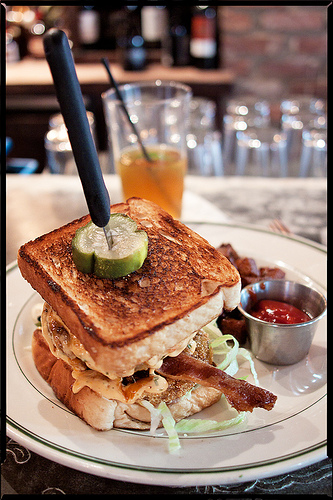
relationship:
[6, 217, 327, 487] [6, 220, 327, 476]
plate has green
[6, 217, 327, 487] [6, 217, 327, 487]
plate has plate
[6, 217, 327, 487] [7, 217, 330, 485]
plate has lines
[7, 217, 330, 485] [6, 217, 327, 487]
lines on plate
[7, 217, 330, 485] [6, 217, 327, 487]
lines are on plate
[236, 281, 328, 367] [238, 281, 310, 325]
cup of ketchup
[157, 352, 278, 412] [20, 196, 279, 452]
bacon in sandwich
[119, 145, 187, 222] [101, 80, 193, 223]
liquid in glass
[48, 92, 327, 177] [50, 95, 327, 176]
glasses in back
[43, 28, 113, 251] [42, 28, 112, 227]
knife has a handle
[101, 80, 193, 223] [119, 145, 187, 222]
glass of liquid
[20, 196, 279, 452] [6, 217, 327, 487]
sandwich on plate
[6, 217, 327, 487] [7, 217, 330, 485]
plate made of lines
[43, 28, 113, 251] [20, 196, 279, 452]
knife stuck in sandwich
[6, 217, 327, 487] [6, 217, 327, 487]
plate color of plate